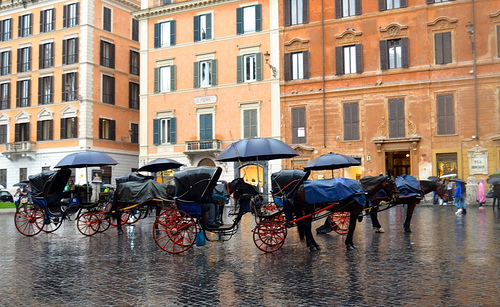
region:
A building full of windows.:
[140, 3, 497, 185]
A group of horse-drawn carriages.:
[15, 144, 457, 245]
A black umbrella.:
[307, 149, 361, 171]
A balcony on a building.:
[1, 142, 40, 159]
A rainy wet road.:
[2, 210, 497, 300]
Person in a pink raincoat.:
[471, 177, 486, 211]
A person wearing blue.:
[450, 175, 467, 207]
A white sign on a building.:
[465, 144, 487, 178]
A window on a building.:
[154, 20, 178, 47]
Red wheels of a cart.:
[152, 205, 201, 252]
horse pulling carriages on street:
[23, 131, 459, 259]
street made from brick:
[5, 240, 492, 301]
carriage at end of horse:
[248, 167, 303, 257]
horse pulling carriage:
[308, 174, 404, 254]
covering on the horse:
[308, 176, 373, 216]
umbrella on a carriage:
[215, 128, 295, 173]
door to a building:
[191, 107, 211, 145]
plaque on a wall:
[469, 150, 490, 179]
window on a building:
[18, 48, 34, 71]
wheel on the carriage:
[154, 213, 202, 252]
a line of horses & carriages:
[11, 135, 481, 242]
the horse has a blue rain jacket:
[299, 165, 393, 212]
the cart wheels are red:
[102, 200, 301, 255]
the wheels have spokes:
[160, 203, 292, 253]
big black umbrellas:
[42, 133, 366, 177]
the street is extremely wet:
[113, 257, 430, 292]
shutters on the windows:
[233, 51, 266, 91]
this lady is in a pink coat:
[476, 172, 486, 216]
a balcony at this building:
[2, 138, 42, 165]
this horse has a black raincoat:
[108, 175, 169, 209]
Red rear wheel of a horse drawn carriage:
[151, 206, 200, 254]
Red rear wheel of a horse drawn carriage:
[10, 200, 49, 237]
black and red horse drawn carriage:
[152, 160, 404, 260]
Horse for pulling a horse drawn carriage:
[290, 172, 400, 250]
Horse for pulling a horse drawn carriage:
[381, 171, 453, 233]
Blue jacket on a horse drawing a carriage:
[300, 174, 372, 215]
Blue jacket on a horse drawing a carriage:
[395, 173, 421, 200]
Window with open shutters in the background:
[150, 63, 180, 93]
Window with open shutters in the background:
[149, 20, 181, 49]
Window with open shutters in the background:
[231, 3, 267, 36]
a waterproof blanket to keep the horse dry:
[301, 177, 366, 204]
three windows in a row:
[153, 43, 265, 94]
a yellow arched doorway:
[237, 162, 265, 201]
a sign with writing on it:
[468, 142, 490, 176]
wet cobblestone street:
[1, 205, 498, 305]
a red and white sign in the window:
[296, 126, 306, 138]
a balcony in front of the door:
[185, 140, 220, 151]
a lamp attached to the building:
[263, 50, 278, 77]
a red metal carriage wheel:
[152, 207, 198, 254]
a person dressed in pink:
[475, 176, 485, 211]